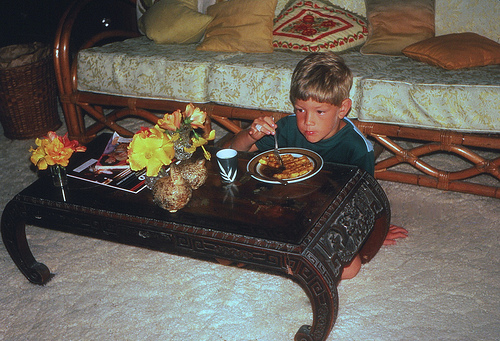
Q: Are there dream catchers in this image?
A: No, there are no dream catchers.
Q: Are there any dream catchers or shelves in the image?
A: No, there are no dream catchers or shelves.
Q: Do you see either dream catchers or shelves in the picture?
A: No, there are no dream catchers or shelves.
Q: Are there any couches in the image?
A: Yes, there is a couch.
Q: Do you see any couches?
A: Yes, there is a couch.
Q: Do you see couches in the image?
A: Yes, there is a couch.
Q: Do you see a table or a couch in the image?
A: Yes, there is a couch.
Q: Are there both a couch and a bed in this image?
A: No, there is a couch but no beds.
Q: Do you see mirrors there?
A: No, there are no mirrors.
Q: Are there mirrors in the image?
A: No, there are no mirrors.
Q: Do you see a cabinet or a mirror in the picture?
A: No, there are no mirrors or cabinets.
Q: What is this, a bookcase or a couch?
A: This is a couch.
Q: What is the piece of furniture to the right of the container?
A: The piece of furniture is a couch.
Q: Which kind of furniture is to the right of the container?
A: The piece of furniture is a couch.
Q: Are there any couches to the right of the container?
A: Yes, there is a couch to the right of the container.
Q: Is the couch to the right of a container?
A: Yes, the couch is to the right of a container.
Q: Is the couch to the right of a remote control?
A: No, the couch is to the right of a container.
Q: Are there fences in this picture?
A: No, there are no fences.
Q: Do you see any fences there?
A: No, there are no fences.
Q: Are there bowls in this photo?
A: No, there are no bowls.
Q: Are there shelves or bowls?
A: No, there are no bowls or shelves.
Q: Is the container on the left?
A: Yes, the container is on the left of the image.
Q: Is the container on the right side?
A: No, the container is on the left of the image.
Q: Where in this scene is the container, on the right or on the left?
A: The container is on the left of the image.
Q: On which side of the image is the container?
A: The container is on the left of the image.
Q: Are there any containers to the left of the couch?
A: Yes, there is a container to the left of the couch.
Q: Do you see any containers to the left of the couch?
A: Yes, there is a container to the left of the couch.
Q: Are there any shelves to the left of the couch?
A: No, there is a container to the left of the couch.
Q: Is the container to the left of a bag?
A: No, the container is to the left of the couch.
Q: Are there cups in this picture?
A: Yes, there is a cup.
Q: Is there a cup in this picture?
A: Yes, there is a cup.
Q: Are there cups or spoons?
A: Yes, there is a cup.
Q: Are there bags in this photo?
A: No, there are no bags.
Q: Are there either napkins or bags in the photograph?
A: No, there are no bags or napkins.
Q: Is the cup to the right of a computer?
A: No, the cup is to the right of a magazine.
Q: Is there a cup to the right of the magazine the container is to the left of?
A: Yes, there is a cup to the right of the magazine.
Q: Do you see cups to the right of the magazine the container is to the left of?
A: Yes, there is a cup to the right of the magazine.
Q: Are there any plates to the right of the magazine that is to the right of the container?
A: No, there is a cup to the right of the magazine.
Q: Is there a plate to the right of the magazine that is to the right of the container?
A: No, there is a cup to the right of the magazine.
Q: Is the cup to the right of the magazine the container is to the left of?
A: Yes, the cup is to the right of the magazine.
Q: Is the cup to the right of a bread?
A: No, the cup is to the right of the magazine.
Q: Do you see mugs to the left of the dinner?
A: No, there is a cup to the left of the dinner.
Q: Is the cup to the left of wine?
A: No, the cup is to the left of the dinner.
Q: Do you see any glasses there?
A: No, there are no glasses.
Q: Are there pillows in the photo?
A: Yes, there are pillows.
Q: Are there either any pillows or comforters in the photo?
A: Yes, there are pillows.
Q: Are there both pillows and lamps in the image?
A: No, there are pillows but no lamps.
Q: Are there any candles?
A: No, there are no candles.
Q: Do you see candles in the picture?
A: No, there are no candles.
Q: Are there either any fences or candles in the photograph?
A: No, there are no candles or fences.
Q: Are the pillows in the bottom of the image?
A: No, the pillows are in the top of the image.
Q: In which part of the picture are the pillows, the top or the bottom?
A: The pillows are in the top of the image.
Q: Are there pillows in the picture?
A: Yes, there are pillows.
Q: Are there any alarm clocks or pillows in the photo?
A: Yes, there are pillows.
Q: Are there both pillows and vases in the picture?
A: Yes, there are both pillows and a vase.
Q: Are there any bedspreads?
A: No, there are no bedspreads.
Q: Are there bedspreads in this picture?
A: No, there are no bedspreads.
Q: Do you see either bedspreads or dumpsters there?
A: No, there are no bedspreads or dumpsters.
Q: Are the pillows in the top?
A: Yes, the pillows are in the top of the image.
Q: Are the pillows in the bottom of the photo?
A: No, the pillows are in the top of the image.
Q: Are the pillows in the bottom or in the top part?
A: The pillows are in the top of the image.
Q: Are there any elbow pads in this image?
A: No, there are no elbow pads.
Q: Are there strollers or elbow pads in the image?
A: No, there are no elbow pads or strollers.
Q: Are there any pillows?
A: Yes, there are pillows.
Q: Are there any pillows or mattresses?
A: Yes, there are pillows.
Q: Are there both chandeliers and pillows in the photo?
A: No, there are pillows but no chandeliers.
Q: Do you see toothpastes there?
A: No, there are no toothpastes.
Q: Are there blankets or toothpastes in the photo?
A: No, there are no toothpastes or blankets.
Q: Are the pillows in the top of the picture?
A: Yes, the pillows are in the top of the image.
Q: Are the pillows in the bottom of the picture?
A: No, the pillows are in the top of the image.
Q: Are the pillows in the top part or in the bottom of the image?
A: The pillows are in the top of the image.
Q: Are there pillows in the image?
A: Yes, there are pillows.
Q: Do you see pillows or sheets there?
A: Yes, there are pillows.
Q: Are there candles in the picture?
A: No, there are no candles.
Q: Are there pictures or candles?
A: No, there are no candles or pictures.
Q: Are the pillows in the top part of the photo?
A: Yes, the pillows are in the top of the image.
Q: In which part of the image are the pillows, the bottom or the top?
A: The pillows are in the top of the image.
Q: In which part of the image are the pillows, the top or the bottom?
A: The pillows are in the top of the image.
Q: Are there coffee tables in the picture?
A: Yes, there is a coffee table.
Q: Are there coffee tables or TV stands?
A: Yes, there is a coffee table.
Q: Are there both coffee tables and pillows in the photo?
A: Yes, there are both a coffee table and a pillow.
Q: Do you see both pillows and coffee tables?
A: Yes, there are both a coffee table and a pillow.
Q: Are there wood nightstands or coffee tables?
A: Yes, there is a wood coffee table.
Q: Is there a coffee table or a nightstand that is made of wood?
A: Yes, the coffee table is made of wood.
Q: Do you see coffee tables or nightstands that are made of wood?
A: Yes, the coffee table is made of wood.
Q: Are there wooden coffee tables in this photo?
A: Yes, there is a wood coffee table.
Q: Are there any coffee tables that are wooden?
A: Yes, there is a coffee table that is wooden.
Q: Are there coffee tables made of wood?
A: Yes, there is a coffee table that is made of wood.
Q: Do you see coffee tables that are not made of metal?
A: Yes, there is a coffee table that is made of wood.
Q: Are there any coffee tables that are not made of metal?
A: Yes, there is a coffee table that is made of wood.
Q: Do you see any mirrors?
A: No, there are no mirrors.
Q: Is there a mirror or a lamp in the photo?
A: No, there are no mirrors or lamps.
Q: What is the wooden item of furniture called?
A: The piece of furniture is a coffee table.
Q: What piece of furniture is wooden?
A: The piece of furniture is a coffee table.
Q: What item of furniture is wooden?
A: The piece of furniture is a coffee table.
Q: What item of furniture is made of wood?
A: The piece of furniture is a coffee table.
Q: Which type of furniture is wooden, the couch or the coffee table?
A: The coffee table is wooden.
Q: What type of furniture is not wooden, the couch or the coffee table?
A: The couch is not wooden.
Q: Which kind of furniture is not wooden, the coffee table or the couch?
A: The couch is not wooden.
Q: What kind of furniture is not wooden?
A: The furniture is a couch.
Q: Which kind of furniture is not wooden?
A: The furniture is a couch.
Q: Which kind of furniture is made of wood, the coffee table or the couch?
A: The coffee table is made of wood.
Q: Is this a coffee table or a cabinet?
A: This is a coffee table.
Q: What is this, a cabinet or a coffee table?
A: This is a coffee table.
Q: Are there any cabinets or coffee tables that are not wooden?
A: No, there is a coffee table but it is wooden.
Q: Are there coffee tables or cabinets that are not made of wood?
A: No, there is a coffee table but it is made of wood.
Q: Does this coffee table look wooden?
A: Yes, the coffee table is wooden.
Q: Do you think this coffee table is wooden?
A: Yes, the coffee table is wooden.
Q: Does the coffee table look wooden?
A: Yes, the coffee table is wooden.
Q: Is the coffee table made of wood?
A: Yes, the coffee table is made of wood.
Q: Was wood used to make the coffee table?
A: Yes, the coffee table is made of wood.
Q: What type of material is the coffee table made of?
A: The coffee table is made of wood.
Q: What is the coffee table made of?
A: The coffee table is made of wood.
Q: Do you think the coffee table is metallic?
A: No, the coffee table is wooden.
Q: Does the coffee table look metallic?
A: No, the coffee table is wooden.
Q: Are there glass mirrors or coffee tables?
A: No, there is a coffee table but it is wooden.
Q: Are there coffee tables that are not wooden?
A: No, there is a coffee table but it is wooden.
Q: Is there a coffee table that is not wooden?
A: No, there is a coffee table but it is wooden.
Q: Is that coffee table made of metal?
A: No, the coffee table is made of wood.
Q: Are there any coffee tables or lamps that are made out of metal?
A: No, there is a coffee table but it is made of wood.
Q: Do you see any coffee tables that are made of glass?
A: No, there is a coffee table but it is made of wood.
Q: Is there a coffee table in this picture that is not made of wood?
A: No, there is a coffee table but it is made of wood.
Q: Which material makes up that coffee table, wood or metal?
A: The coffee table is made of wood.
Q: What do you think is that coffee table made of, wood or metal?
A: The coffee table is made of wood.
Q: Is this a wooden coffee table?
A: Yes, this is a wooden coffee table.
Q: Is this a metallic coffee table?
A: No, this is a wooden coffee table.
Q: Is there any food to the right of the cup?
A: No, there is dinner to the right of the cup.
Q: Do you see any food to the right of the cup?
A: No, there is dinner to the right of the cup.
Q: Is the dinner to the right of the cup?
A: Yes, the dinner is to the right of the cup.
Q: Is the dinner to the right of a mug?
A: No, the dinner is to the right of the cup.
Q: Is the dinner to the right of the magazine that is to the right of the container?
A: Yes, the dinner is to the right of the magazine.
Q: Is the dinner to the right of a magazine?
A: Yes, the dinner is to the right of a magazine.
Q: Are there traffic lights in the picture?
A: No, there are no traffic lights.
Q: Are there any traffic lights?
A: No, there are no traffic lights.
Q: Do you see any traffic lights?
A: No, there are no traffic lights.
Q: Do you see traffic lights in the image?
A: No, there are no traffic lights.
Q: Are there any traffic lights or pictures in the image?
A: No, there are no traffic lights or pictures.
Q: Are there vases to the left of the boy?
A: Yes, there is a vase to the left of the boy.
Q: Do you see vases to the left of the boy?
A: Yes, there is a vase to the left of the boy.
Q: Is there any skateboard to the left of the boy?
A: No, there is a vase to the left of the boy.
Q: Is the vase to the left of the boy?
A: Yes, the vase is to the left of the boy.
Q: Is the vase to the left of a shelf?
A: No, the vase is to the left of the boy.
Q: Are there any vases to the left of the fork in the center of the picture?
A: Yes, there is a vase to the left of the fork.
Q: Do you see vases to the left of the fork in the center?
A: Yes, there is a vase to the left of the fork.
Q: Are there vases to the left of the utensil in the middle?
A: Yes, there is a vase to the left of the fork.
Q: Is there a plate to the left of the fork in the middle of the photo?
A: No, there is a vase to the left of the fork.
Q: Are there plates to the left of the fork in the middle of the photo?
A: No, there is a vase to the left of the fork.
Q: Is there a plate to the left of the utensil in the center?
A: No, there is a vase to the left of the fork.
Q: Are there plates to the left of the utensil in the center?
A: No, there is a vase to the left of the fork.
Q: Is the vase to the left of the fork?
A: Yes, the vase is to the left of the fork.